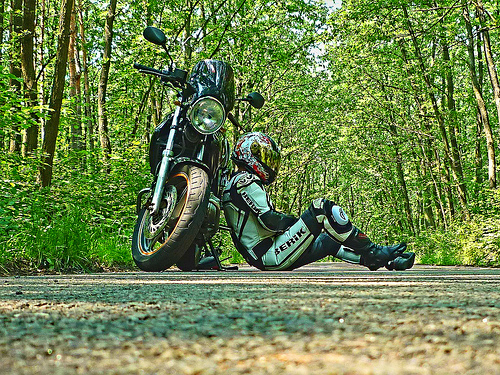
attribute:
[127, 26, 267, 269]
motor bike — shiny, parked, black, partial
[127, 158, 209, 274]
tire — rubber, black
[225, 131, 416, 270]
motor bike driver — sitting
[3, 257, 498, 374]
road — gravel covered, brown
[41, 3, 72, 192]
tree — grouping, green leaved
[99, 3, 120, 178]
tree — tall, green leaved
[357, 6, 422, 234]
tree — tall, green leaved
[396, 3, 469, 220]
tree — tall, green leaved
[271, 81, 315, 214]
tree — tall, green leaved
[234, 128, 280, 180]
helmet — red, black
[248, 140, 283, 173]
lens — yellow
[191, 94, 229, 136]
headlight — shiny, large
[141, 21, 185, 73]
rear view mirror — on right side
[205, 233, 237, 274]
kick stand — black, metal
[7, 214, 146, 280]
grass — green, tall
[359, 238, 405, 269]
boot — black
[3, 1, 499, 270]
forest — partial, green